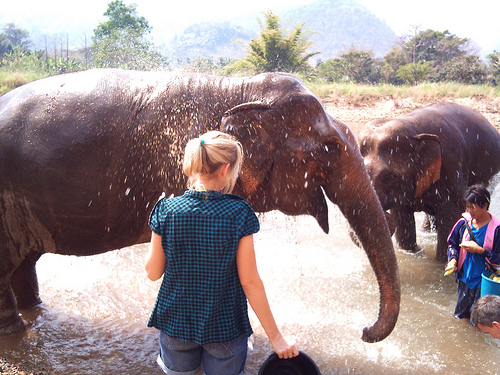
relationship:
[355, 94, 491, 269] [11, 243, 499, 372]
elephant in water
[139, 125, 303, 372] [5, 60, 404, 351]
woman next to elephant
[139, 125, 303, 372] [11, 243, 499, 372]
woman in water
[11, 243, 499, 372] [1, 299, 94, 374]
water has splashes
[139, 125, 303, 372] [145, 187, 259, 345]
woman wearing shirt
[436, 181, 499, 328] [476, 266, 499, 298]
lady holding bucket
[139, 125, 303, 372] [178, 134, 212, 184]
girl has ponytail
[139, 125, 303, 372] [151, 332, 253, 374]
girl wearing shorts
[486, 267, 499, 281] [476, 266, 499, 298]
sponges in bucket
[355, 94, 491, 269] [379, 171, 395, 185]
elephant has eye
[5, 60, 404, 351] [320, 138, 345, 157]
elephant has eye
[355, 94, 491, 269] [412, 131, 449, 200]
elephant has ear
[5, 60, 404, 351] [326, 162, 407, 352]
elephant has trunk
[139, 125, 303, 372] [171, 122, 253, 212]
person has head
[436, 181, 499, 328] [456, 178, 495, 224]
person has head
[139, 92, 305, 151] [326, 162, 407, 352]
water spraying from trunk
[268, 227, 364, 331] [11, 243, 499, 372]
light brightly on water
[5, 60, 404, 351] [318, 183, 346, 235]
elephant has mouth open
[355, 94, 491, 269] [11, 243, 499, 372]
elephant standing in water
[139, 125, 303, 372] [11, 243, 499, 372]
person standing in water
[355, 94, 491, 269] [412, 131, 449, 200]
elephant has two colors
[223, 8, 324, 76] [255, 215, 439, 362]
tree past pond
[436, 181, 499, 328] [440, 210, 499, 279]
lady wearing jacket